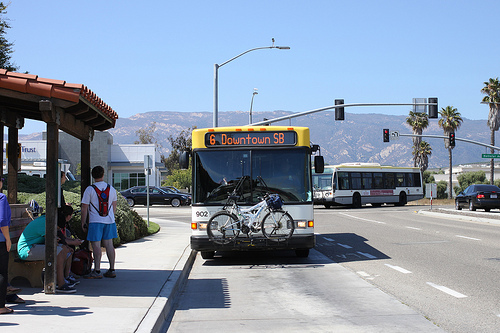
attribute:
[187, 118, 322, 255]
city bus — large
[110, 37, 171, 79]
clouds — white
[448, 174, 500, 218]
car — black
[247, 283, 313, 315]
street — gray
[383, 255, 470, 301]
stripes — gray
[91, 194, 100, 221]
tshirt — white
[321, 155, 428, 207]
bus — yellow, white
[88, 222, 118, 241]
shorts — blue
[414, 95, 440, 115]
sign — white, green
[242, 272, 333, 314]
road — gray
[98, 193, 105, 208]
backpack — small